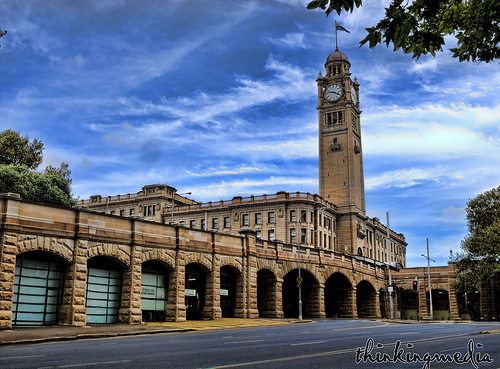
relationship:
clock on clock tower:
[350, 83, 360, 106] [314, 18, 368, 210]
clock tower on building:
[317, 18, 366, 215] [72, 18, 407, 264]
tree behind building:
[2, 128, 80, 204] [76, 186, 421, 276]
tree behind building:
[366, 3, 498, 64] [76, 186, 421, 276]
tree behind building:
[453, 186, 499, 322] [76, 186, 421, 276]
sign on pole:
[294, 273, 304, 285] [296, 281, 305, 323]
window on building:
[265, 207, 274, 222] [3, 12, 499, 367]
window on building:
[238, 209, 251, 229] [3, 12, 499, 367]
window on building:
[288, 206, 298, 223] [3, 12, 499, 367]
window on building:
[208, 216, 222, 229] [3, 12, 499, 367]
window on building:
[125, 205, 139, 222] [3, 12, 499, 367]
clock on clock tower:
[323, 81, 345, 103] [317, 18, 366, 215]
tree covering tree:
[453, 186, 499, 322] [305, 3, 498, 336]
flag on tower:
[330, 20, 352, 53] [315, 17, 370, 216]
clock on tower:
[323, 81, 345, 103] [315, 17, 370, 216]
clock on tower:
[348, 82, 360, 105] [315, 17, 370, 216]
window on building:
[266, 210, 278, 225] [72, 18, 407, 264]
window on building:
[257, 210, 262, 225] [72, 18, 407, 264]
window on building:
[242, 215, 249, 228] [72, 18, 407, 264]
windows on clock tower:
[323, 109, 344, 130] [317, 20, 366, 215]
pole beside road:
[423, 238, 441, 320] [27, 318, 437, 361]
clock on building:
[317, 78, 353, 110] [292, 22, 397, 314]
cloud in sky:
[158, 80, 313, 152] [24, 18, 483, 222]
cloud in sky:
[388, 92, 489, 169] [24, 18, 483, 222]